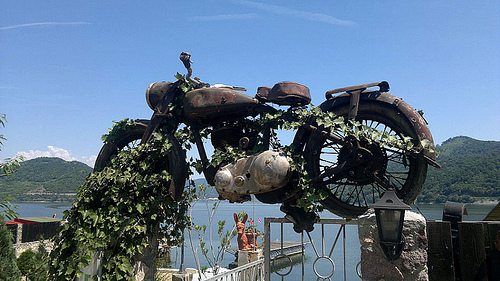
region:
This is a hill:
[10, 140, 64, 180]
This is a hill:
[56, 137, 98, 190]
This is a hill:
[431, 105, 476, 192]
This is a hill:
[478, 122, 491, 156]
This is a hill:
[58, 140, 106, 222]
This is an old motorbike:
[74, 52, 456, 224]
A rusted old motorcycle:
[84, 64, 439, 233]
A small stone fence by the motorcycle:
[257, 216, 386, 280]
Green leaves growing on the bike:
[54, 162, 179, 275]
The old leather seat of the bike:
[251, 68, 318, 112]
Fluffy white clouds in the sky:
[14, 145, 78, 165]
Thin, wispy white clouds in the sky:
[202, 2, 364, 27]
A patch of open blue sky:
[13, 45, 102, 120]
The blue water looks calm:
[205, 201, 267, 213]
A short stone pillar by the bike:
[361, 208, 429, 280]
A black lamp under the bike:
[369, 184, 412, 261]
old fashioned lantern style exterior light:
[376, 179, 408, 259]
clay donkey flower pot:
[233, 212, 262, 251]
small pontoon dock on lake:
[229, 238, 309, 269]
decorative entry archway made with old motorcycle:
[89, 51, 441, 216]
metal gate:
[263, 217, 361, 280]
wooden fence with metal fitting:
[426, 200, 499, 276]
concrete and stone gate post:
[359, 201, 429, 279]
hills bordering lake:
[0, 135, 498, 201]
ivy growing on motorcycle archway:
[3, 52, 440, 279]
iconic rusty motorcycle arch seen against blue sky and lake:
[2, 0, 497, 280]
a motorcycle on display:
[69, 39, 429, 210]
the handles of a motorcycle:
[175, 48, 218, 80]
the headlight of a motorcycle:
[138, 70, 175, 110]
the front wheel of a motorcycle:
[107, 107, 175, 168]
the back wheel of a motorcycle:
[310, 81, 423, 198]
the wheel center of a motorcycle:
[340, 135, 375, 180]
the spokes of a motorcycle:
[327, 173, 361, 198]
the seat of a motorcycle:
[249, 77, 312, 109]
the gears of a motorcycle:
[202, 124, 267, 152]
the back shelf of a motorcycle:
[325, 65, 387, 105]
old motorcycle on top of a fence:
[31, 43, 428, 203]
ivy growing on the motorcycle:
[65, 82, 452, 224]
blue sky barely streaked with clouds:
[181, 2, 467, 58]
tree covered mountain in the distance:
[444, 138, 489, 199]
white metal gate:
[256, 214, 358, 274]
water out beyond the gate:
[193, 200, 233, 256]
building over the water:
[251, 235, 311, 267]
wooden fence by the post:
[431, 210, 499, 250]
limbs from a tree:
[191, 197, 232, 279]